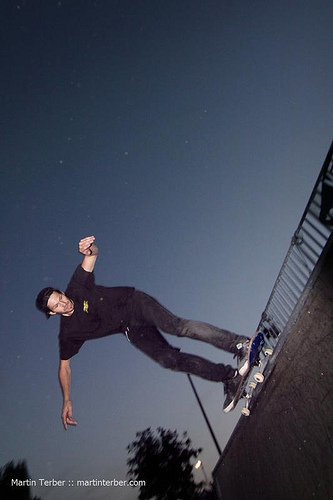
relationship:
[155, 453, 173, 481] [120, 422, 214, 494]
leaves on tree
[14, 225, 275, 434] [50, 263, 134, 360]
man wearing shirt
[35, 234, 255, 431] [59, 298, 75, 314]
man with beard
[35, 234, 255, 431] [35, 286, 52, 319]
man wearing hat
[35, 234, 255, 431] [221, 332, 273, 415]
man riding skateboard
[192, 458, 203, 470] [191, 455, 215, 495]
light on lightpost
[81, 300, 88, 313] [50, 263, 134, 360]
mark on shirt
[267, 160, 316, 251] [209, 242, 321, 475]
metal fence at top of ramp